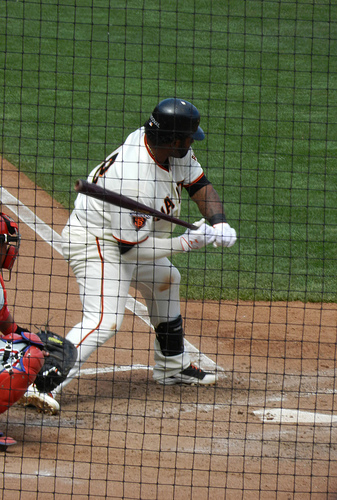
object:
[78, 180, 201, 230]
bat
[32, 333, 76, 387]
glove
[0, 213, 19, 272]
mask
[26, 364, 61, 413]
shoes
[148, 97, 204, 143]
helmet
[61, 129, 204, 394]
uniform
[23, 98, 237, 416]
player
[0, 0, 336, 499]
ground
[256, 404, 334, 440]
base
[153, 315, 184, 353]
gear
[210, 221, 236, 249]
gloves